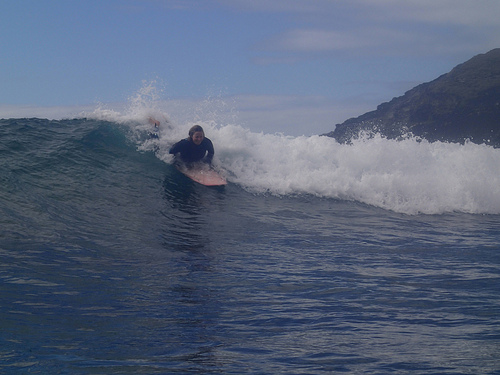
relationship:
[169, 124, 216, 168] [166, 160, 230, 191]
surfer riding on top of surfboard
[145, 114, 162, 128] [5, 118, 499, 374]
feet are in water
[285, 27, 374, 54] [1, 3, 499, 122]
cloud floating in sky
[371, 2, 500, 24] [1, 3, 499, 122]
cloud floating in sky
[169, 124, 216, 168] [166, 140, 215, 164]
surfer wearing wetsuit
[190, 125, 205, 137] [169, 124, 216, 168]
hair on head of surfer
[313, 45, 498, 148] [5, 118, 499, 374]
hill next to water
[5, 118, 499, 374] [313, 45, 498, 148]
water next to hill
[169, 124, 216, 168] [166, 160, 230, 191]
surfer on top of surfboard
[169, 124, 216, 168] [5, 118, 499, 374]
surfer on water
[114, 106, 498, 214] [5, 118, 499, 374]
wave on top of water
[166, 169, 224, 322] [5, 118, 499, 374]
reflection on surface of water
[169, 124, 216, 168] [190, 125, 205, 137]
surfer has hair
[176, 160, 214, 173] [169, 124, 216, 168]
hands belong to surfer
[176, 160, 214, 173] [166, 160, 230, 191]
hands are on top of surfboard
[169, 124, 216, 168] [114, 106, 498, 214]
surfer has caught a wave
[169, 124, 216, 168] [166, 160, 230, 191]
surfer lying on top of surfboard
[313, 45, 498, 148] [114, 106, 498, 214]
hill behind wave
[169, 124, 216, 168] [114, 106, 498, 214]
surfer catching a wave